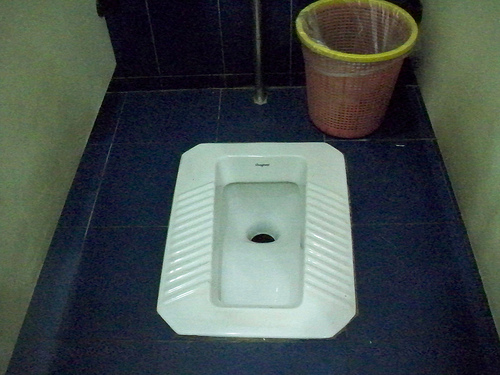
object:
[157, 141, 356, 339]
toilet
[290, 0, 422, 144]
dust bin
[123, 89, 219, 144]
tile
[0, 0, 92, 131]
wall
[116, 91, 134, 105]
line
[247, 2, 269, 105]
pipe